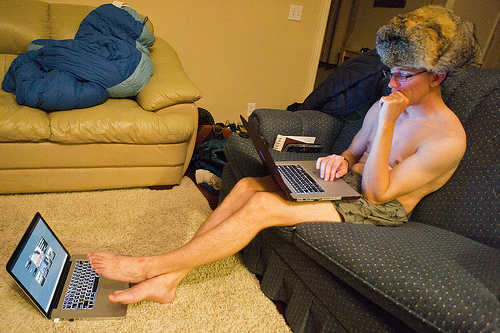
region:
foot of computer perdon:
[88, 248, 151, 283]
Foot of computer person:
[104, 277, 179, 307]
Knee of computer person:
[236, 177, 257, 194]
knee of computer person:
[250, 191, 277, 218]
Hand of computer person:
[377, 90, 411, 121]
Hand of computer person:
[315, 153, 350, 181]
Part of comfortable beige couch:
[49, 116, 146, 134]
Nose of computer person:
[386, 79, 399, 90]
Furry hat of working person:
[369, 4, 484, 73]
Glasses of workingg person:
[378, 67, 425, 82]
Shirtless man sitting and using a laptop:
[106, 14, 466, 302]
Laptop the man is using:
[238, 118, 353, 205]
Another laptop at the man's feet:
[4, 200, 143, 327]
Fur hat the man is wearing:
[368, 4, 473, 70]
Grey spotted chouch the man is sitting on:
[214, 63, 499, 330]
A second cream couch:
[0, 0, 197, 194]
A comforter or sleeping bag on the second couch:
[0, 0, 165, 118]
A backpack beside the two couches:
[197, 110, 234, 147]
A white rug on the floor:
[1, 172, 291, 329]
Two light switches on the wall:
[268, 0, 308, 30]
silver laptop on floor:
[6, 201, 132, 331]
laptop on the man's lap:
[240, 100, 360, 205]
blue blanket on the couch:
[5, 0, 150, 110]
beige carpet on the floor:
[65, 190, 190, 242]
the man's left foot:
[85, 245, 147, 280]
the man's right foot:
[102, 275, 187, 305]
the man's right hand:
[311, 152, 352, 178]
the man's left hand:
[375, 90, 406, 115]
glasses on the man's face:
[386, 68, 431, 82]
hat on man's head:
[375, 6, 485, 73]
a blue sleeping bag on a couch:
[21, 7, 196, 130]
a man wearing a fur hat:
[365, 0, 470, 146]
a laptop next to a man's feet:
[15, 195, 139, 328]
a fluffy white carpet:
[192, 292, 233, 331]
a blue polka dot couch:
[406, 245, 480, 318]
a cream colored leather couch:
[82, 122, 157, 183]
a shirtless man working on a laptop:
[209, 12, 491, 284]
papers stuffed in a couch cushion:
[265, 117, 319, 157]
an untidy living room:
[18, 10, 480, 307]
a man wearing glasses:
[376, 64, 433, 113]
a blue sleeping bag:
[8, 10, 153, 103]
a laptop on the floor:
[5, 211, 130, 318]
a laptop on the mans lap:
[238, 105, 360, 200]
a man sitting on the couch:
[93, 7, 476, 305]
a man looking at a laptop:
[89, 9, 471, 311]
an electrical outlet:
[244, 100, 256, 113]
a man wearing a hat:
[379, 21, 464, 108]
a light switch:
[286, 3, 303, 23]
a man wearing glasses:
[379, 20, 454, 100]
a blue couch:
[232, 23, 487, 317]